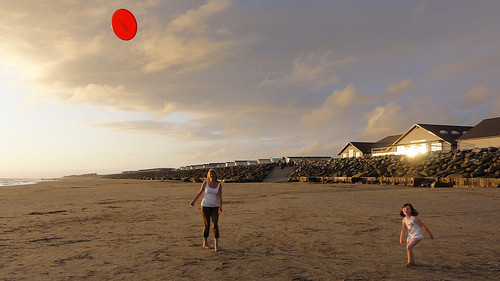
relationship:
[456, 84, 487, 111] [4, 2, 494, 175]
clouds in sky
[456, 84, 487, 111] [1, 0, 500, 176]
clouds in sky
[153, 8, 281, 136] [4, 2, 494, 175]
clouds in sky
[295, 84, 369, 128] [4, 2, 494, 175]
clouds in sky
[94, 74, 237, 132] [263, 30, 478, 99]
clouds in sky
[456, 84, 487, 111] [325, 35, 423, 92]
clouds in sky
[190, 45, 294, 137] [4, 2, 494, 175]
clouds in sky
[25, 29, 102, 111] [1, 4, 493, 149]
clouds in sky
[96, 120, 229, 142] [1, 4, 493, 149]
clouds in sky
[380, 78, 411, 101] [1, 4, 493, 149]
clouds in sky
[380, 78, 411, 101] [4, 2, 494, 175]
clouds in sky